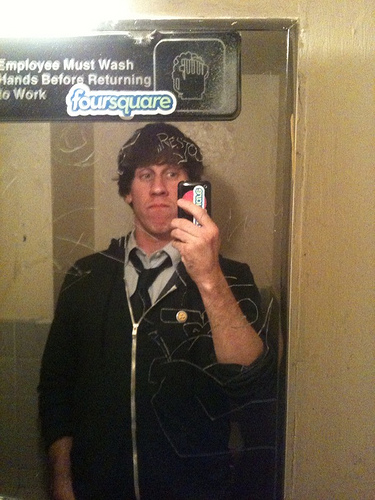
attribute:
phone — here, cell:
[174, 178, 209, 236]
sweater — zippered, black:
[30, 215, 268, 487]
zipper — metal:
[115, 253, 169, 498]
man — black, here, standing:
[25, 129, 277, 500]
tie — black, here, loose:
[129, 248, 170, 322]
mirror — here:
[6, 20, 276, 498]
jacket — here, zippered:
[30, 200, 265, 492]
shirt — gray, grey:
[121, 233, 176, 316]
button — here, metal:
[173, 301, 195, 333]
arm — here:
[169, 204, 272, 390]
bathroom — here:
[5, 4, 372, 498]